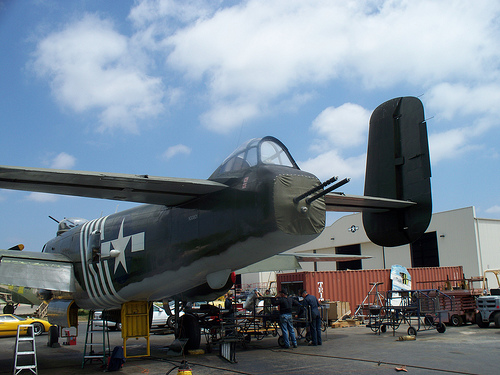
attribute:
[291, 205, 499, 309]
hangar — airplane, one, large, white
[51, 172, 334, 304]
airplane — large, worked on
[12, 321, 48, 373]
ladder — one, small, shiny, aluminum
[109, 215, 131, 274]
star — large, white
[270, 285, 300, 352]
man — one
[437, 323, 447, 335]
tire — black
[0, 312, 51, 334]
car — yellow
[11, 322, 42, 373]
ladder — metal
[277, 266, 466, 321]
container — red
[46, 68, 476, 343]
airplane — fighter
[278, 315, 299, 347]
jeans — blue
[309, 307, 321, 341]
pants — blue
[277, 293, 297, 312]
shirt — black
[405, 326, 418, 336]
black wheels — round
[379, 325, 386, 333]
black wheels — round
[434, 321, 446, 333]
black wheels — round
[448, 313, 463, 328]
black wheels — round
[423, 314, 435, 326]
black wheels — round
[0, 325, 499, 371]
ground —  grey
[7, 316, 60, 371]
ladder — small, silver, metal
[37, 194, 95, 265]
propeller — back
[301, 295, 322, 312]
blue shirt — blue 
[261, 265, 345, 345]
men — performing maintenance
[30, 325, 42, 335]
tire — black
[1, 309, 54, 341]
car — white, yellow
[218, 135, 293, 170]
domed window — one, airplane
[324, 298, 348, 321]
boxes — cardboard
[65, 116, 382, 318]
airplane — large, gray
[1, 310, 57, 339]
car — yellow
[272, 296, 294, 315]
shirt — dark, short sleeved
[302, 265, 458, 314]
dumpster — red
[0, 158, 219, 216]
wing — one, large, gray, airplane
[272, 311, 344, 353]
pants — blue